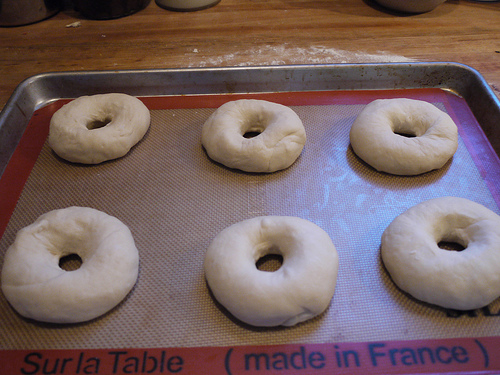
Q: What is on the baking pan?
A: Bagels.